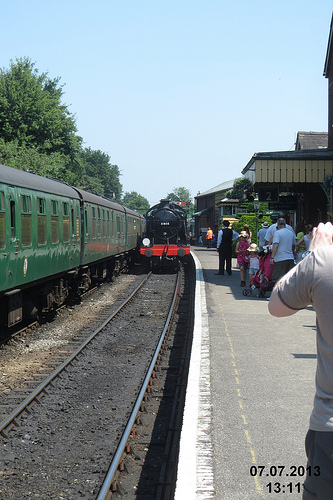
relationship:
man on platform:
[204, 225, 212, 248] [184, 243, 316, 494]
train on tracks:
[1, 161, 149, 345] [8, 272, 183, 492]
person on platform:
[217, 218, 238, 276] [175, 243, 331, 497]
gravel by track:
[1, 261, 144, 498] [1, 250, 188, 499]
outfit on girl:
[233, 236, 257, 255] [231, 225, 277, 293]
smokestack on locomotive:
[161, 196, 171, 211] [141, 190, 191, 274]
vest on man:
[206, 228, 213, 238] [205, 226, 213, 246]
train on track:
[107, 198, 208, 257] [1, 250, 188, 499]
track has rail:
[1, 250, 188, 499] [0, 265, 153, 435]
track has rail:
[1, 250, 188, 499] [92, 259, 184, 498]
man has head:
[262, 211, 305, 300] [275, 216, 287, 229]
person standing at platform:
[217, 218, 238, 276] [175, 243, 331, 497]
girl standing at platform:
[235, 231, 250, 288] [175, 243, 331, 497]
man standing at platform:
[266, 218, 297, 302] [175, 243, 331, 497]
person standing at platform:
[257, 220, 269, 254] [175, 243, 331, 497]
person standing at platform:
[246, 243, 259, 285] [175, 243, 331, 497]